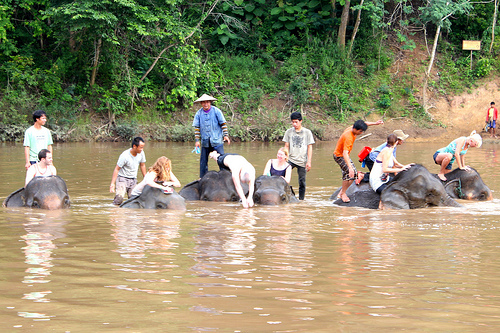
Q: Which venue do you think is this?
A: This is a river.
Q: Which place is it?
A: It is a river.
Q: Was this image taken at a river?
A: Yes, it was taken in a river.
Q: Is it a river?
A: Yes, it is a river.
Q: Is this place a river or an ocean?
A: It is a river.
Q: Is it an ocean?
A: No, it is a river.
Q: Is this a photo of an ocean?
A: No, the picture is showing a river.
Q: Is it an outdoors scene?
A: Yes, it is outdoors.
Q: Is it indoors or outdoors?
A: It is outdoors.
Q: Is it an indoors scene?
A: No, it is outdoors.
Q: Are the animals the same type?
A: Yes, all the animals are elephants.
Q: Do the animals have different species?
A: No, all the animals are elephants.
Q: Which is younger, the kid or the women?
A: The kid is younger than the women.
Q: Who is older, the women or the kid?
A: The women is older than the kid.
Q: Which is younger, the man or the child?
A: The child is younger than the man.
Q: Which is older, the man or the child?
A: The man is older than the child.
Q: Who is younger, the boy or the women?
A: The boy is younger than the women.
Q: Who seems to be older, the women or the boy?
A: The women is older than the boy.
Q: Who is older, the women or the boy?
A: The women is older than the boy.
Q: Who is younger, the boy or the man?
A: The boy is younger than the man.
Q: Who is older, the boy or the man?
A: The man is older than the boy.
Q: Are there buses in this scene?
A: No, there are no buses.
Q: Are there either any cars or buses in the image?
A: No, there are no buses or cars.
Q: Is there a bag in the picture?
A: No, there are no bags.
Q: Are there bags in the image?
A: No, there are no bags.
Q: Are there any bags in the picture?
A: No, there are no bags.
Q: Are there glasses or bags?
A: No, there are no bags or glasses.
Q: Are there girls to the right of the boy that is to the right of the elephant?
A: Yes, there is a girl to the right of the boy.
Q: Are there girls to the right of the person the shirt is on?
A: Yes, there is a girl to the right of the boy.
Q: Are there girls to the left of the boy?
A: No, the girl is to the right of the boy.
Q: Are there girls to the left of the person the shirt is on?
A: No, the girl is to the right of the boy.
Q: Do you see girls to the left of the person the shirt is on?
A: No, the girl is to the right of the boy.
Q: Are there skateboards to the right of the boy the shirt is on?
A: No, there is a girl to the right of the boy.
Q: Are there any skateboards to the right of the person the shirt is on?
A: No, there is a girl to the right of the boy.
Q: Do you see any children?
A: Yes, there is a child.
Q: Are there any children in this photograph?
A: Yes, there is a child.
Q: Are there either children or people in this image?
A: Yes, there is a child.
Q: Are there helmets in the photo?
A: No, there are no helmets.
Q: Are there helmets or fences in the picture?
A: No, there are no helmets or fences.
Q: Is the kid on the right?
A: Yes, the kid is on the right of the image.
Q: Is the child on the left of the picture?
A: No, the child is on the right of the image.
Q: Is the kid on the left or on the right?
A: The kid is on the right of the image.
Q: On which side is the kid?
A: The kid is on the right of the image.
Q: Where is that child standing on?
A: The child is standing on the shore.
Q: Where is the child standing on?
A: The child is standing on the shore.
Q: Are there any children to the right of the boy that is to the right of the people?
A: Yes, there is a child to the right of the boy.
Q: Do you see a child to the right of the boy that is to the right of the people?
A: Yes, there is a child to the right of the boy.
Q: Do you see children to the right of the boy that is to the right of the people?
A: Yes, there is a child to the right of the boy.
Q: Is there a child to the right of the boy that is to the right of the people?
A: Yes, there is a child to the right of the boy.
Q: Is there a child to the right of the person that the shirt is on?
A: Yes, there is a child to the right of the boy.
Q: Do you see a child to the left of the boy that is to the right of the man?
A: No, the child is to the right of the boy.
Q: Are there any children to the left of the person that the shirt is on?
A: No, the child is to the right of the boy.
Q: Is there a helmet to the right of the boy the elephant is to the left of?
A: No, there is a child to the right of the boy.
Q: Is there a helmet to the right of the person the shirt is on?
A: No, there is a child to the right of the boy.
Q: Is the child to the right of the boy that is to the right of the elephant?
A: Yes, the child is to the right of the boy.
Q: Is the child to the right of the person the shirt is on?
A: Yes, the child is to the right of the boy.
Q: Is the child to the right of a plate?
A: No, the child is to the right of the boy.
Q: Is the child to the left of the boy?
A: No, the child is to the right of the boy.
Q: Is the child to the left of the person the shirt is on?
A: No, the child is to the right of the boy.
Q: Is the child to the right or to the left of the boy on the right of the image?
A: The child is to the right of the boy.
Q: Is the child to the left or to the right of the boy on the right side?
A: The child is to the right of the boy.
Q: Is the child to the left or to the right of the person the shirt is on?
A: The child is to the right of the boy.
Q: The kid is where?
A: The kid is on the shore.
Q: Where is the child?
A: The kid is on the shore.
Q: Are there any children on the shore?
A: Yes, there is a child on the shore.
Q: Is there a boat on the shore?
A: No, there is a child on the shore.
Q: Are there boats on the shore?
A: No, there is a child on the shore.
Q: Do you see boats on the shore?
A: No, there is a child on the shore.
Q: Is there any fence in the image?
A: No, there are no fences.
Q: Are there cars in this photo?
A: No, there are no cars.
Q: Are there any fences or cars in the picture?
A: No, there are no cars or fences.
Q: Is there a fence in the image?
A: No, there are no fences.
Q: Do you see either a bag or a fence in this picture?
A: No, there are no fences or bags.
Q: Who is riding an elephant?
A: The people are riding an elephant.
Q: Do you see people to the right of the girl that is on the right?
A: No, the people are to the left of the girl.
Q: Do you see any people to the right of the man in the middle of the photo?
A: Yes, there are people to the right of the man.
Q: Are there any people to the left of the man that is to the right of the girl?
A: No, the people are to the right of the man.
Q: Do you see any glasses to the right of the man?
A: No, there are people to the right of the man.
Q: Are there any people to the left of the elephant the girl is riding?
A: Yes, there are people to the left of the elephant.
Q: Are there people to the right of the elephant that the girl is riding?
A: No, the people are to the left of the elephant.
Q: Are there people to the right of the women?
A: Yes, there are people to the right of the women.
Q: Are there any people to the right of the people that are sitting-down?
A: Yes, there are people to the right of the women.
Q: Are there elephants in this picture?
A: Yes, there is an elephant.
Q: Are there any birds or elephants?
A: Yes, there is an elephant.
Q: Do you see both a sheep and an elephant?
A: No, there is an elephant but no sheep.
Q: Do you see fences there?
A: No, there are no fences.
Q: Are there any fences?
A: No, there are no fences.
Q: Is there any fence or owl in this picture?
A: No, there are no fences or owls.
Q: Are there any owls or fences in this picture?
A: No, there are no fences or owls.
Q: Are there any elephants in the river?
A: Yes, there is an elephant in the river.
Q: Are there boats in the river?
A: No, there is an elephant in the river.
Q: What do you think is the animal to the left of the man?
A: The animal is an elephant.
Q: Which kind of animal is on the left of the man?
A: The animal is an elephant.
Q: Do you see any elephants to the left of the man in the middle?
A: Yes, there is an elephant to the left of the man.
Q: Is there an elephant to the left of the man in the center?
A: Yes, there is an elephant to the left of the man.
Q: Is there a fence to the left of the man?
A: No, there is an elephant to the left of the man.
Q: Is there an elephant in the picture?
A: Yes, there is an elephant.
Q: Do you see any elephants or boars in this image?
A: Yes, there is an elephant.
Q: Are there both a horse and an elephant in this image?
A: No, there is an elephant but no horses.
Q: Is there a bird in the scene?
A: No, there are no birds.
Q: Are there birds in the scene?
A: No, there are no birds.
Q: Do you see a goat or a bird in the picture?
A: No, there are no birds or goats.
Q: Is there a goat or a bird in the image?
A: No, there are no birds or goats.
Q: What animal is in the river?
A: The animal is an elephant.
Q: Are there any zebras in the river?
A: No, there is an elephant in the river.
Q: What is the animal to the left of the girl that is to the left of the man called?
A: The animal is an elephant.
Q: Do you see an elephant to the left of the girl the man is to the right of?
A: Yes, there is an elephant to the left of the girl.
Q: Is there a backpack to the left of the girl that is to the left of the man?
A: No, there is an elephant to the left of the girl.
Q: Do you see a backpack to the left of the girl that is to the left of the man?
A: No, there is an elephant to the left of the girl.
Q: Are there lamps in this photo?
A: No, there are no lamps.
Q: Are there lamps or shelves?
A: No, there are no lamps or shelves.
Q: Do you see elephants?
A: Yes, there is an elephant.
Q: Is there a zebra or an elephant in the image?
A: Yes, there is an elephant.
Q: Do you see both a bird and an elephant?
A: No, there is an elephant but no birds.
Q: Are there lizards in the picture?
A: No, there are no lizards.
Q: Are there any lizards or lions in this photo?
A: No, there are no lizards or lions.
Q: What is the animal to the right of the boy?
A: The animal is an elephant.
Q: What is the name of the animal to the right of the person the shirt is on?
A: The animal is an elephant.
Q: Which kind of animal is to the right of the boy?
A: The animal is an elephant.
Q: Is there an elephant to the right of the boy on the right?
A: Yes, there is an elephant to the right of the boy.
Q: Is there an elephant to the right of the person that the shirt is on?
A: Yes, there is an elephant to the right of the boy.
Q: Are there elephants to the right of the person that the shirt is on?
A: Yes, there is an elephant to the right of the boy.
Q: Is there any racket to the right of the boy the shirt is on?
A: No, there is an elephant to the right of the boy.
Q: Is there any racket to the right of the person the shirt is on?
A: No, there is an elephant to the right of the boy.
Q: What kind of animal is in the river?
A: The animal is an elephant.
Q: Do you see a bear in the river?
A: No, there is an elephant in the river.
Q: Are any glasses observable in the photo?
A: No, there are no glasses.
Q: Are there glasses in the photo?
A: No, there are no glasses.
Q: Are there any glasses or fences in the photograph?
A: No, there are no glasses or fences.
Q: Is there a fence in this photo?
A: No, there are no fences.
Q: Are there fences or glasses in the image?
A: No, there are no fences or glasses.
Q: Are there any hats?
A: Yes, there is a hat.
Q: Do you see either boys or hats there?
A: Yes, there is a hat.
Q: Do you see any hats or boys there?
A: Yes, there is a hat.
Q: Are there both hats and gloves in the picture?
A: No, there is a hat but no gloves.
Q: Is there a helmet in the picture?
A: No, there are no helmets.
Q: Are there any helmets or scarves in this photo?
A: No, there are no helmets or scarves.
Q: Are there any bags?
A: No, there are no bags.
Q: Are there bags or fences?
A: No, there are no bags or fences.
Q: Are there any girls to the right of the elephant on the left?
A: Yes, there is a girl to the right of the elephant.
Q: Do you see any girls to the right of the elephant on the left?
A: Yes, there is a girl to the right of the elephant.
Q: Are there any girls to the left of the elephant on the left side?
A: No, the girl is to the right of the elephant.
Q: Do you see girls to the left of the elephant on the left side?
A: No, the girl is to the right of the elephant.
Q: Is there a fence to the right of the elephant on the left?
A: No, there is a girl to the right of the elephant.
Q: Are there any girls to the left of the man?
A: Yes, there is a girl to the left of the man.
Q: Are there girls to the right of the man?
A: No, the girl is to the left of the man.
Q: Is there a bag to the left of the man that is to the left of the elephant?
A: No, there is a girl to the left of the man.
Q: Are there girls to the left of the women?
A: Yes, there is a girl to the left of the women.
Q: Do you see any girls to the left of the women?
A: Yes, there is a girl to the left of the women.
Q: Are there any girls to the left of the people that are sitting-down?
A: Yes, there is a girl to the left of the women.